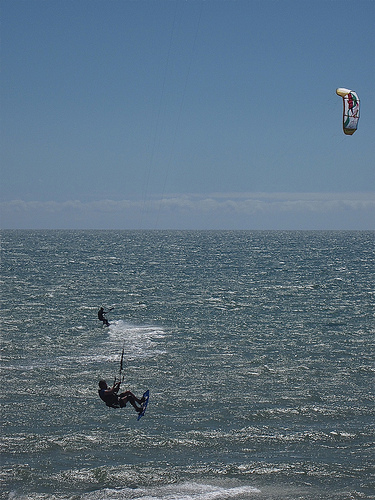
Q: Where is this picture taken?
A: On the ocean.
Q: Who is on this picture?
A: Two people.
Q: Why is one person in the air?
A: He is jumping off the waves.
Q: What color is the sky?
A: Blue.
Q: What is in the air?
A: A kite used by the person to surf.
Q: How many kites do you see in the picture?
A: One.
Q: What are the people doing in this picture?
A: Kitesurfing.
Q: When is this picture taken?
A: During the day.